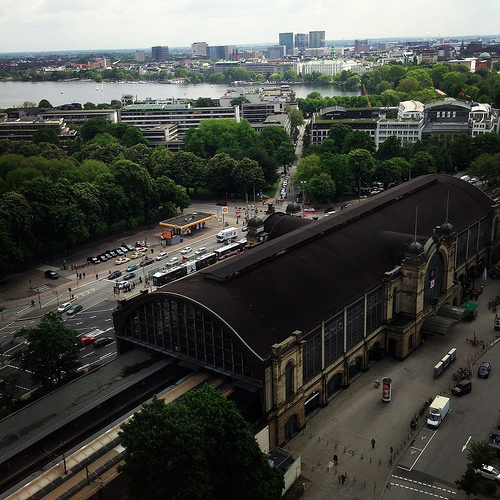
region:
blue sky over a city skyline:
[5, 0, 495, 76]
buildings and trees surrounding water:
[5, 61, 375, 123]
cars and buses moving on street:
[71, 205, 236, 291]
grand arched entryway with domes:
[400, 191, 460, 352]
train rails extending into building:
[5, 332, 240, 493]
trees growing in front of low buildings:
[11, 101, 291, 226]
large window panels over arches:
[305, 280, 385, 415]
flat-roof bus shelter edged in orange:
[150, 205, 216, 245]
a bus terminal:
[111, 173, 498, 441]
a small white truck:
[422, 393, 451, 432]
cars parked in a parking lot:
[83, 238, 148, 265]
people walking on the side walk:
[331, 434, 383, 486]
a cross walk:
[385, 471, 464, 498]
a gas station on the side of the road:
[161, 205, 229, 242]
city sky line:
[3, 25, 499, 87]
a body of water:
[1, 78, 366, 112]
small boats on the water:
[52, 81, 168, 98]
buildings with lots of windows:
[1, 96, 498, 159]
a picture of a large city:
[17, 31, 469, 415]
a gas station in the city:
[157, 184, 232, 240]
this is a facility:
[184, 201, 494, 412]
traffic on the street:
[77, 244, 236, 295]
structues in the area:
[30, 77, 482, 164]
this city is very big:
[61, 34, 478, 90]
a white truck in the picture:
[411, 382, 465, 437]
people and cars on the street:
[57, 257, 175, 302]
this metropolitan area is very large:
[19, 104, 488, 166]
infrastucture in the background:
[367, 28, 498, 87]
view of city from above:
[8, 31, 485, 497]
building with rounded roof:
[118, 161, 492, 389]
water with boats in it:
[8, 70, 343, 105]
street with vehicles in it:
[91, 236, 159, 288]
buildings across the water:
[158, 28, 349, 69]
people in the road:
[322, 439, 374, 489]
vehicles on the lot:
[86, 240, 137, 266]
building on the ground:
[306, 92, 496, 154]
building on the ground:
[9, 93, 296, 150]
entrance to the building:
[413, 240, 468, 348]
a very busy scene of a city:
[19, 20, 464, 375]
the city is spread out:
[15, 43, 489, 349]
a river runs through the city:
[15, 60, 407, 127]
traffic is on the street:
[32, 210, 278, 319]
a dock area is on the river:
[203, 69, 300, 102]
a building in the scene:
[313, 79, 499, 148]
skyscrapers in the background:
[253, 26, 360, 72]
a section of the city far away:
[349, 26, 499, 78]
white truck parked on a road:
[424, 391, 453, 424]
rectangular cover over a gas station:
[159, 207, 214, 229]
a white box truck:
[423, 392, 454, 429]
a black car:
[477, 355, 493, 381]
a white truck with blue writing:
[211, 225, 243, 242]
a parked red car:
[74, 328, 96, 346]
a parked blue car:
[89, 332, 117, 347]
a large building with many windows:
[5, 162, 497, 498]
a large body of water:
[4, 74, 372, 113]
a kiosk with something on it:
[377, 374, 394, 405]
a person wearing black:
[369, 434, 379, 453]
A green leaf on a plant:
[73, 168, 79, 173]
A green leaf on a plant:
[70, 177, 74, 179]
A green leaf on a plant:
[105, 171, 109, 173]